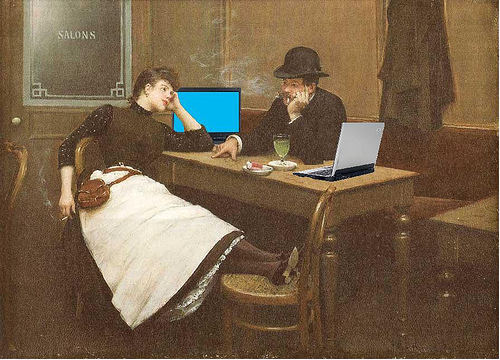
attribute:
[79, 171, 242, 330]
skirt — white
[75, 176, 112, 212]
bag — brown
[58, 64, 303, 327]
woman — Relaxed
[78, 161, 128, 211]
purse — brown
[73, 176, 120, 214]
bag — brown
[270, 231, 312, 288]
heels — black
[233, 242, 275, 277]
stockings — black